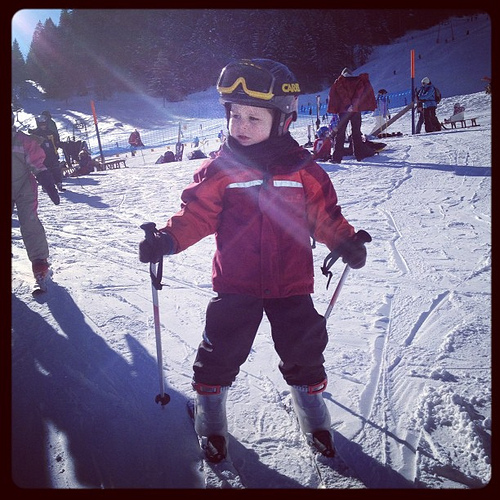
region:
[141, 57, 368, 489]
a young child skiing in snow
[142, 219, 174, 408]
a white snow pole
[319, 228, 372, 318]
a white snow pole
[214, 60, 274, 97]
yellow and black protective eyewear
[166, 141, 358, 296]
a red snow jacket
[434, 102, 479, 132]
a red snow sled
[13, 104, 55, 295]
a snow skier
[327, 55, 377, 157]
a person standing in snow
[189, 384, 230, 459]
a grey snow boot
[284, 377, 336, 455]
a grey snow boot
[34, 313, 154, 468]
a shadow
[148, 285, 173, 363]
a ski pole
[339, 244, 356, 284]
child holding a ski pole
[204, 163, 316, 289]
child wearing a red jacket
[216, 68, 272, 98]
ski goggles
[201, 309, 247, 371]
grey pants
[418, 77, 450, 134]
a person standing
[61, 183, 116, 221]
a shadow on the snow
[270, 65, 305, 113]
child is wearing a helmet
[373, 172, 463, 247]
the snow is white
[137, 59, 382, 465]
The infant wearing skis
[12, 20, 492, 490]
Snow filled skiing grounds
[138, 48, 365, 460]
The kid wearing a helmet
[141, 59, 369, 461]
The kid wearing red jacket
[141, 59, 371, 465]
The kid with dark protective glasses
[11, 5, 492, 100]
The mist filled bushes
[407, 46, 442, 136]
The person standing next to a pole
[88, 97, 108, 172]
A blue and red mounted pole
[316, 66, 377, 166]
The person wearing a red jacket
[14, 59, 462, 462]
People wearing protective gear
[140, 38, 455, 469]
A young boy going skiing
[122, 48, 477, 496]
a little boy wearing ski gear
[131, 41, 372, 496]
a boy standing on skiis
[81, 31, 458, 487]
a boy on a slope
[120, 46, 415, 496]
a boy going skiing on a slope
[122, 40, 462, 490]
a boy standing in the snow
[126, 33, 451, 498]
a boy from head to toe in ski gear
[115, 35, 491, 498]
a boy wearing a helmet and warm clothing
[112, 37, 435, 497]
a boy preparing to ski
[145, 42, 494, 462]
a boy wearing a red snow jacket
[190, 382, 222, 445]
the boys left skate boot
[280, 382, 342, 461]
the boys right skate boot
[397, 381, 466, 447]
the snow on the ground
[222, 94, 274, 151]
the boys face in the cold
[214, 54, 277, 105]
the boys yellow goggles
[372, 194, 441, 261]
tracks in the snow on the ground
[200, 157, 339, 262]
the boys red coat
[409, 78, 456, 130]
a person wearing blue in the background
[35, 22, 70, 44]
the green trees in the distance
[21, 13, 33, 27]
the bright blue sky